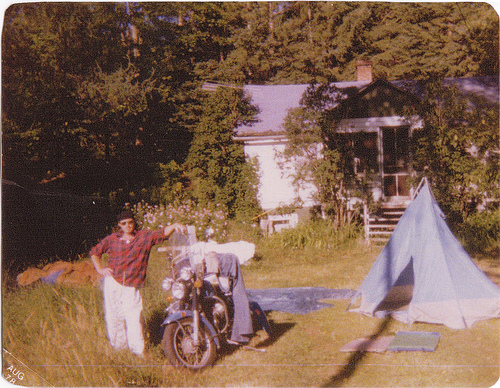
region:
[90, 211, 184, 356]
A man poses for a picture next to a motorcycle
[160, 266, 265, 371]
A blue motorcycle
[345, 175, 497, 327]
A light blue tent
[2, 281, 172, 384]
Tall weeds and grass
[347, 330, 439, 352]
Two mats on the grass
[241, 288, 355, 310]
A blue rain tarp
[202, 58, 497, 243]
A white house with a blue roof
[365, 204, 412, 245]
Stair case leading to the patio of a house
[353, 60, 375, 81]
A brick chimney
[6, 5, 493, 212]
A very dense forest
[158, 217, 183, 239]
the hand of a man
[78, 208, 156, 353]
a man standing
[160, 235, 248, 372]
a parked motorbike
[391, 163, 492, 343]
a tent pitched on the ground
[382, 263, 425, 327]
the entrance of a tent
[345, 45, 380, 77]
the chimney of a building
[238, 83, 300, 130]
the roof of a building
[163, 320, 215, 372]
the wheel of a motorbike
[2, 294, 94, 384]
grass on the ground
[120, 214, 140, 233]
the head of a man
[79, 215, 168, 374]
man stands near cycle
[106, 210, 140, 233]
man has black hat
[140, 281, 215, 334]
blue frame on bike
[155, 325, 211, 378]
black wheel on bike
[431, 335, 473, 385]
green grass near tipi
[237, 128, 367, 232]
white exterior on house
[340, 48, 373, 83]
red brick chimney on roof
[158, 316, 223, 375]
tire on a cycle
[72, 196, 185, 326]
man next to a bike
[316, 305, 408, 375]
shadow on the ground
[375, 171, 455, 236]
top of the tent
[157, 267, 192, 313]
light on the bike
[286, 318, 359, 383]
grass next to bike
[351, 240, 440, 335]
inner part of the tent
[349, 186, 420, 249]
steps to the door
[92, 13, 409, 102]
trees behind the house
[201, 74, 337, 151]
roof of the building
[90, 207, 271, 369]
Man standing next to his motorcycle.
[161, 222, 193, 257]
Bare arm resting on motorcycle plexiglass windshield.